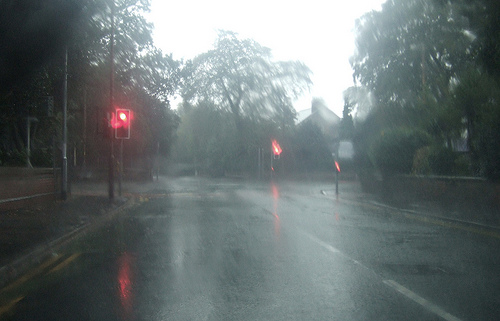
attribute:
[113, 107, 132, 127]
light — shining, red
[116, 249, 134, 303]
light — red, shining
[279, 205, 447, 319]
line — white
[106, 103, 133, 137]
street light — red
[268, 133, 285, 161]
street light — red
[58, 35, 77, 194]
pole — silver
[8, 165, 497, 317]
road — black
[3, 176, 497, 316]
street — slick, wet, rain-wet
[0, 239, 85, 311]
yellow lines — on the side of the road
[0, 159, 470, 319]
no cars — on the road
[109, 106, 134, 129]
top light — on the traffic light, is shining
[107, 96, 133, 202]
traffic light — on a pole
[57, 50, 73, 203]
pole — coming out of the sidewalk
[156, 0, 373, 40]
light — in daytime sky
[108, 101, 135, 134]
traffic light — glowing red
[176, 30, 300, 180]
tree — overlooking street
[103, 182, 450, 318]
wet pavement — of street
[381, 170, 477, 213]
wall — under bushes along sidewalk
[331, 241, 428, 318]
white line — on road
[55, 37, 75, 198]
pole — next to wall on sidewalk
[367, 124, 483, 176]
trimmed bushes — behind wall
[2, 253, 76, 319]
double lines — on street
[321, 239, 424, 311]
white line — marking road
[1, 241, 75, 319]
yellow lines — marking road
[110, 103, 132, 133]
red light — illuminated on traffic signal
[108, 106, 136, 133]
traffic signal — attached to pole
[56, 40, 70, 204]
large/gray pole — on sidewalk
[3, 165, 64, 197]
brick wall — next to sidewalk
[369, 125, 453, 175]
green bushes — near wall